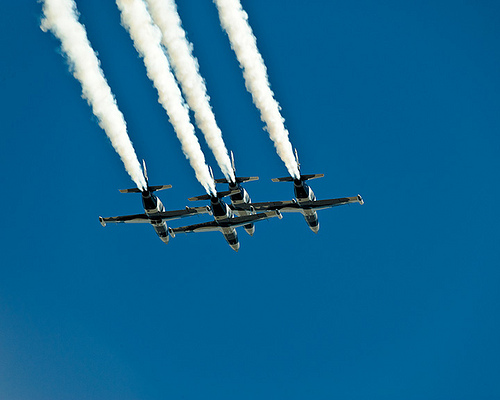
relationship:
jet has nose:
[209, 198, 246, 249] [234, 245, 242, 255]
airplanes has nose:
[95, 171, 203, 247] [156, 232, 171, 245]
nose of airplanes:
[307, 216, 321, 234] [268, 149, 363, 238]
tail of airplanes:
[118, 160, 171, 192] [268, 149, 363, 238]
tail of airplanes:
[269, 149, 326, 181] [268, 149, 363, 238]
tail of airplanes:
[210, 169, 261, 189] [268, 149, 363, 238]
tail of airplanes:
[187, 181, 239, 200] [268, 149, 363, 238]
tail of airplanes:
[118, 160, 171, 192] [95, 171, 203, 247]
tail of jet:
[269, 149, 326, 181] [261, 148, 367, 238]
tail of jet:
[210, 169, 261, 189] [216, 165, 278, 234]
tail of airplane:
[187, 181, 239, 200] [160, 172, 285, 251]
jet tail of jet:
[210, 173, 260, 185] [182, 149, 298, 235]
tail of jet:
[67, 17, 358, 155] [129, 169, 440, 246]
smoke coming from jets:
[37, 0, 304, 175] [101, 174, 368, 253]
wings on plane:
[95, 202, 214, 230] [93, 158, 210, 246]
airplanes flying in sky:
[95, 171, 203, 247] [1, 4, 496, 397]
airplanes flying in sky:
[268, 149, 363, 238] [1, 4, 496, 397]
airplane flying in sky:
[180, 173, 297, 238] [1, 4, 496, 397]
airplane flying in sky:
[160, 185, 285, 251] [1, 4, 496, 397]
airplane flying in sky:
[94, 181, 219, 248] [1, 4, 496, 397]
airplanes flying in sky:
[95, 149, 363, 255] [1, 4, 496, 397]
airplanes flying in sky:
[91, 171, 367, 253] [352, 103, 485, 340]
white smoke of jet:
[214, 1, 308, 180] [253, 170, 365, 233]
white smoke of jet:
[113, 0, 250, 195] [185, 176, 277, 235]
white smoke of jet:
[38, 1, 158, 193] [95, 185, 207, 243]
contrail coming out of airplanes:
[213, 0, 302, 179] [268, 149, 363, 238]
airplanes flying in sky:
[268, 149, 363, 238] [300, 6, 492, 124]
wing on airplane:
[165, 204, 211, 219] [98, 186, 210, 243]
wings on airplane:
[95, 202, 150, 230] [98, 186, 210, 243]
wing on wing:
[240, 199, 296, 214] [165, 204, 211, 219]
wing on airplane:
[232, 210, 284, 229] [169, 188, 283, 251]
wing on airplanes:
[313, 194, 363, 214] [268, 149, 363, 238]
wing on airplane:
[231, 205, 287, 232] [163, 161, 284, 255]